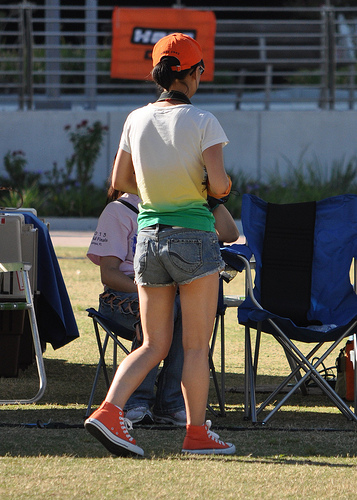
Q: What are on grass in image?
A: Blue and black lawn chair.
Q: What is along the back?
A: Brush.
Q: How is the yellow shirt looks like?
A: Trendy.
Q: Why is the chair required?
A: Sit.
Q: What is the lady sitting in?
A: Folding chair.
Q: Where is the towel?
A: Over back of chair.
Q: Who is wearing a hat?
A: A lady.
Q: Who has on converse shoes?
A: A lady.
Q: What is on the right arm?
A: Wrist band.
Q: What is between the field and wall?
A: Sidewalk.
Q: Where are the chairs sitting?
A: In grass.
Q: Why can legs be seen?
A: Wearing of shorts.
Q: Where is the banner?
A: On gate.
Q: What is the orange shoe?
A: Sneakers.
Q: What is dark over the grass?
A: Shade.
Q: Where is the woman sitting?
A: Chair.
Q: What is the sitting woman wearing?
A: Pink tee shirt.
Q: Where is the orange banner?
A: On fence.